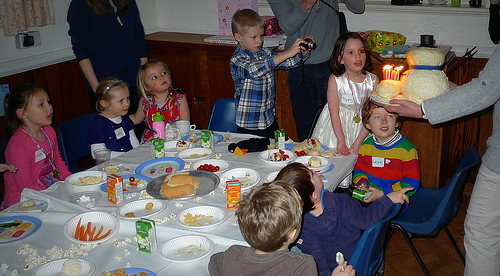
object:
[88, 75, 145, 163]
children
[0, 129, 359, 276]
cloth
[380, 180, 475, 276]
floor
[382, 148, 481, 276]
chair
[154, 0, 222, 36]
wall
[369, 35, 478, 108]
cake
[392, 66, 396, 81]
candles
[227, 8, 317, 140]
boy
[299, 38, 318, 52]
camera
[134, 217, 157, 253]
box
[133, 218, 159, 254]
juice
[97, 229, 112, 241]
carrots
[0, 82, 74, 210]
girl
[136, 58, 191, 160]
girl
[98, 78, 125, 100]
headband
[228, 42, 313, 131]
shirt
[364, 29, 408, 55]
presents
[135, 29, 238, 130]
counter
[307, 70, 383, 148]
dress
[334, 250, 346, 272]
spoon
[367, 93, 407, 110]
platter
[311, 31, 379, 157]
girls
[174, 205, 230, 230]
plate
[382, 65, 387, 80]
candle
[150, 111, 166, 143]
bottle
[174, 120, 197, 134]
mug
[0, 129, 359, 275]
table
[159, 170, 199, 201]
buns